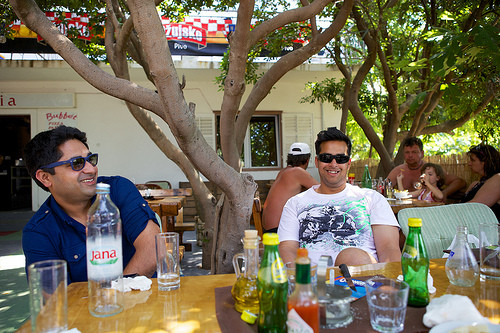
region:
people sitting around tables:
[23, 100, 493, 294]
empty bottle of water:
[83, 176, 124, 318]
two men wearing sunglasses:
[26, 116, 386, 258]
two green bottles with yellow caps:
[263, 216, 428, 332]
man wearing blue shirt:
[18, 123, 170, 283]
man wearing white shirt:
[269, 129, 397, 267]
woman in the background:
[458, 136, 495, 209]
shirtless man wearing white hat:
[262, 133, 307, 223]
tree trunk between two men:
[55, 38, 315, 254]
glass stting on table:
[361, 276, 412, 332]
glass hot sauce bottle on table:
[286, 248, 327, 330]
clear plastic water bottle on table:
[74, 182, 134, 314]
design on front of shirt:
[289, 200, 371, 243]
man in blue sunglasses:
[29, 132, 110, 182]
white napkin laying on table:
[109, 265, 160, 300]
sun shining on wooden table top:
[140, 300, 212, 330]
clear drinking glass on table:
[359, 277, 415, 331]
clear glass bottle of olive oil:
[226, 217, 263, 319]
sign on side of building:
[31, 111, 91, 126]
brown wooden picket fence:
[443, 148, 468, 173]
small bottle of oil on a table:
[228, 225, 263, 315]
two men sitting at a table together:
[18, 123, 400, 279]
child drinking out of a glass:
[408, 160, 445, 203]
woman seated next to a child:
[458, 137, 498, 207]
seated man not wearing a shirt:
[256, 140, 321, 230]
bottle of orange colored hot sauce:
[281, 245, 316, 330]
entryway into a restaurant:
[0, 105, 40, 255]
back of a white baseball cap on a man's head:
[282, 137, 312, 169]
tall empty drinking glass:
[152, 230, 182, 292]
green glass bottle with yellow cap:
[254, 231, 290, 331]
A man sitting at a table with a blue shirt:
[20, 126, 172, 306]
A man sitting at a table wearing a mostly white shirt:
[275, 127, 402, 267]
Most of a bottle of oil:
[230, 229, 260, 326]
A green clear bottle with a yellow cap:
[401, 218, 436, 308]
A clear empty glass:
[152, 231, 182, 290]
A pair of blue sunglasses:
[38, 153, 98, 173]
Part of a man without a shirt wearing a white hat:
[260, 141, 317, 236]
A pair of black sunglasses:
[316, 151, 350, 164]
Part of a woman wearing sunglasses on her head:
[457, 143, 498, 218]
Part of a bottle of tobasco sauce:
[285, 249, 320, 331]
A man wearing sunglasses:
[26, 126, 114, 198]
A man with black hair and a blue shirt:
[30, 132, 115, 274]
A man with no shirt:
[269, 153, 308, 188]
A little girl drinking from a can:
[410, 160, 442, 197]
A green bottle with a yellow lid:
[398, 210, 429, 307]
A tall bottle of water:
[82, 182, 124, 319]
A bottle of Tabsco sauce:
[282, 245, 324, 331]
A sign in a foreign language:
[158, 9, 212, 46]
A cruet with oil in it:
[228, 231, 260, 309]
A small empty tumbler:
[361, 270, 406, 331]